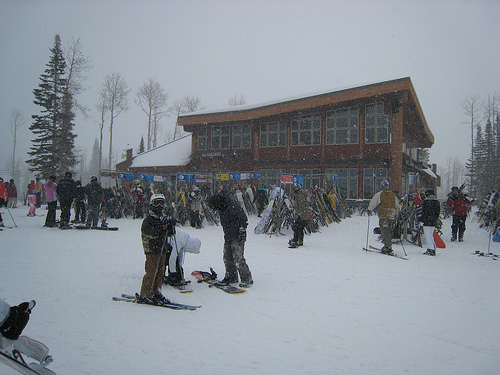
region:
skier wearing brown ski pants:
[110, 188, 204, 315]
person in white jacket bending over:
[166, 228, 204, 295]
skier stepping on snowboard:
[192, 184, 257, 299]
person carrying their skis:
[449, 179, 474, 241]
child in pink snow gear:
[22, 187, 39, 217]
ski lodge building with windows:
[109, 70, 440, 218]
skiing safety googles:
[150, 197, 167, 209]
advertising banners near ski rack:
[94, 168, 266, 183]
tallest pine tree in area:
[22, 29, 82, 202]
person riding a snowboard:
[285, 178, 313, 248]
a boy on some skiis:
[113, 184, 202, 319]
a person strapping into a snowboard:
[186, 186, 255, 297]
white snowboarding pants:
[420, 216, 441, 256]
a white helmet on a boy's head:
[143, 187, 168, 216]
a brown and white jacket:
[366, 180, 401, 222]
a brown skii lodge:
[102, 66, 450, 222]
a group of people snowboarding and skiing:
[24, 140, 491, 356]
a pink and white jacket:
[44, 177, 59, 203]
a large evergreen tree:
[28, 38, 81, 193]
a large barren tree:
[87, 67, 134, 171]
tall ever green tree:
[30, 28, 82, 190]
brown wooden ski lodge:
[108, 70, 441, 233]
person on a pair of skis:
[111, 187, 205, 317]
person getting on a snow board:
[180, 184, 260, 296]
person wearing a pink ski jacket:
[31, 174, 62, 234]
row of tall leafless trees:
[62, 30, 245, 196]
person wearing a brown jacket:
[357, 173, 412, 265]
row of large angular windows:
[174, 96, 402, 152]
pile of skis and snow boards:
[248, 176, 357, 247]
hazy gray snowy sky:
[3, 0, 498, 202]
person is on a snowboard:
[213, 172, 250, 299]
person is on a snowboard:
[86, 178, 114, 236]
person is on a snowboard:
[42, 177, 60, 237]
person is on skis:
[141, 195, 179, 320]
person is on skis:
[360, 190, 393, 275]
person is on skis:
[0, 182, 9, 237]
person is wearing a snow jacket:
[211, 198, 251, 244]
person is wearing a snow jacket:
[141, 198, 170, 255]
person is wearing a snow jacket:
[369, 183, 400, 214]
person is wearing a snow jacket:
[58, 173, 73, 207]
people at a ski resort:
[26, 74, 484, 341]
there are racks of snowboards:
[252, 176, 356, 246]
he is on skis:
[107, 181, 204, 326]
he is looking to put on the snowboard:
[180, 177, 283, 316]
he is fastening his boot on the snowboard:
[158, 203, 210, 301]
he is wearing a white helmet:
[112, 171, 208, 334]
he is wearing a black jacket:
[196, 170, 259, 317]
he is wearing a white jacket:
[162, 222, 207, 290]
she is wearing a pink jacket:
[36, 165, 59, 227]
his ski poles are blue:
[119, 177, 203, 325]